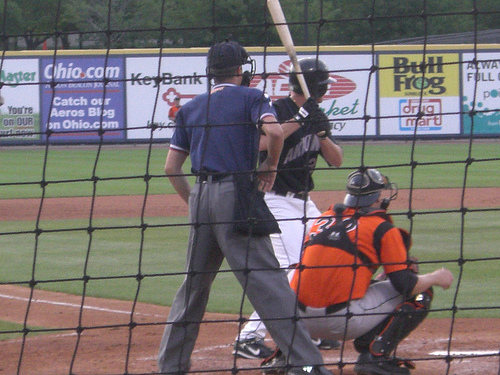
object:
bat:
[265, 0, 328, 142]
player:
[229, 59, 344, 361]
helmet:
[288, 56, 338, 90]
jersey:
[257, 95, 342, 195]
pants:
[233, 187, 325, 338]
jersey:
[287, 202, 417, 315]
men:
[154, 42, 333, 375]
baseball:
[0, 137, 499, 371]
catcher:
[258, 169, 452, 375]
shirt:
[167, 84, 278, 181]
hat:
[204, 38, 259, 87]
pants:
[157, 175, 326, 371]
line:
[0, 290, 169, 323]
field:
[0, 46, 498, 374]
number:
[310, 214, 357, 242]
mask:
[237, 53, 256, 87]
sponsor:
[42, 61, 124, 89]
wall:
[0, 42, 500, 146]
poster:
[124, 53, 375, 143]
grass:
[0, 138, 500, 202]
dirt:
[0, 191, 177, 221]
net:
[1, 1, 497, 375]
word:
[283, 133, 321, 165]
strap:
[300, 201, 415, 269]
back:
[289, 203, 378, 307]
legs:
[154, 225, 332, 375]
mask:
[368, 174, 401, 211]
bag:
[232, 186, 282, 237]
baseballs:
[241, 217, 265, 237]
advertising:
[377, 54, 460, 99]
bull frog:
[393, 55, 446, 96]